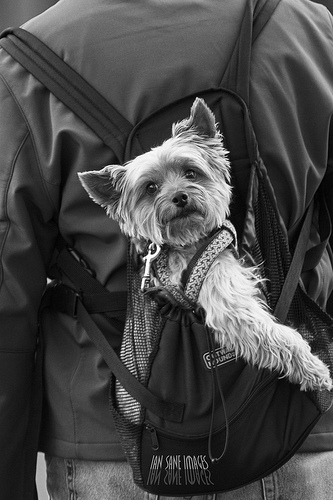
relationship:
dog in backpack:
[77, 98, 330, 395] [6, 3, 330, 498]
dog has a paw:
[77, 98, 330, 395] [295, 364, 330, 395]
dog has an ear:
[77, 98, 330, 395] [169, 98, 229, 141]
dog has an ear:
[77, 98, 330, 395] [76, 162, 122, 205]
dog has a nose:
[77, 98, 330, 395] [169, 193, 192, 210]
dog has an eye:
[77, 98, 330, 395] [183, 167, 200, 181]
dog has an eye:
[77, 98, 330, 395] [142, 181, 159, 193]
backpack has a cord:
[6, 3, 330, 498] [206, 332, 231, 464]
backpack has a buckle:
[6, 3, 330, 498] [68, 290, 85, 317]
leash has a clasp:
[138, 230, 238, 311] [140, 243, 161, 296]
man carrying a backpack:
[4, 0, 332, 499] [6, 3, 330, 498]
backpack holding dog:
[6, 3, 330, 498] [77, 98, 330, 395]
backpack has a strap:
[6, 3, 330, 498] [2, 24, 138, 157]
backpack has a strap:
[6, 3, 330, 498] [217, 1, 281, 105]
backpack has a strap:
[6, 3, 330, 498] [275, 207, 318, 317]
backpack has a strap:
[6, 3, 330, 498] [80, 310, 117, 386]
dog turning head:
[77, 98, 330, 395] [79, 96, 232, 251]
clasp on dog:
[140, 243, 161, 296] [77, 98, 330, 395]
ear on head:
[169, 98, 229, 141] [79, 96, 232, 251]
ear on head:
[76, 162, 122, 205] [79, 96, 232, 251]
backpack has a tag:
[6, 3, 330, 498] [150, 290, 200, 307]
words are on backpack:
[145, 452, 217, 488] [6, 3, 330, 498]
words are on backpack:
[204, 349, 238, 370] [6, 3, 330, 498]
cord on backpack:
[206, 332, 231, 464] [6, 3, 330, 498]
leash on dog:
[138, 230, 238, 311] [77, 98, 330, 395]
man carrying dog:
[4, 0, 332, 499] [77, 98, 330, 395]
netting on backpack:
[116, 273, 157, 419] [6, 3, 330, 498]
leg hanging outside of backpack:
[206, 259, 332, 392] [6, 3, 330, 498]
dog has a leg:
[77, 98, 330, 395] [206, 259, 332, 392]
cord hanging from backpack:
[206, 332, 231, 464] [6, 3, 330, 498]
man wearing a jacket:
[4, 0, 332, 499] [6, 5, 332, 458]